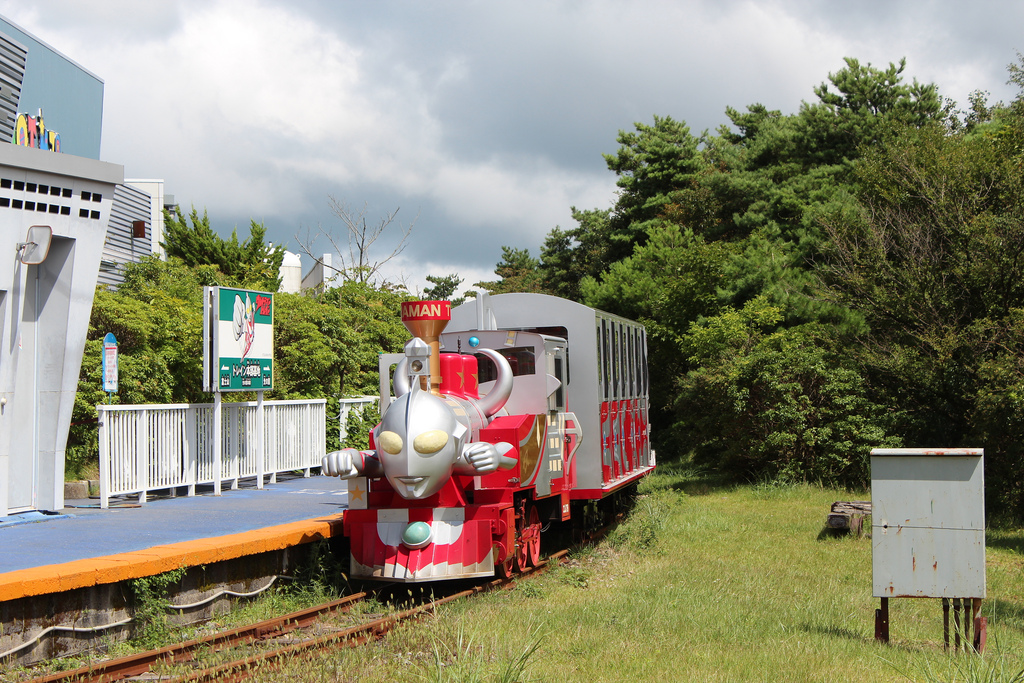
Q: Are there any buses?
A: No, there are no buses.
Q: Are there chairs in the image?
A: No, there are no chairs.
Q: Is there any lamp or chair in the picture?
A: No, there are no chairs or lamps.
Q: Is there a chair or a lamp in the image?
A: No, there are no chairs or lamps.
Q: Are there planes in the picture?
A: No, there are no planes.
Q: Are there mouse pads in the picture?
A: No, there are no mouse pads.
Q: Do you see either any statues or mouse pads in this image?
A: No, there are no mouse pads or statues.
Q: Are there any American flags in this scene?
A: No, there are no American flags.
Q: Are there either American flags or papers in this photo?
A: No, there are no American flags or papers.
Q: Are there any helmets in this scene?
A: No, there are no helmets.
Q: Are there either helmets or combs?
A: No, there are no helmets or combs.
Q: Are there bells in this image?
A: No, there are no bells.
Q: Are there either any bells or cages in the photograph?
A: No, there are no bells or cages.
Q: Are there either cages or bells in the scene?
A: No, there are no bells or cages.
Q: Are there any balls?
A: No, there are no balls.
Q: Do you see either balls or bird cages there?
A: No, there are no balls or bird cages.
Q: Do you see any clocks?
A: No, there are no clocks.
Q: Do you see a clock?
A: No, there are no clocks.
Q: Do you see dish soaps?
A: No, there are no dish soaps.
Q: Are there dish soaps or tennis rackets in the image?
A: No, there are no dish soaps or tennis rackets.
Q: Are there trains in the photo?
A: Yes, there is a train.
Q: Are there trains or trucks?
A: Yes, there is a train.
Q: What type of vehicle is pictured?
A: The vehicle is a train.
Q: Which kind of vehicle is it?
A: The vehicle is a train.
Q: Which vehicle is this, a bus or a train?
A: That is a train.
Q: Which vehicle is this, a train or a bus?
A: That is a train.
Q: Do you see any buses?
A: No, there are no buses.